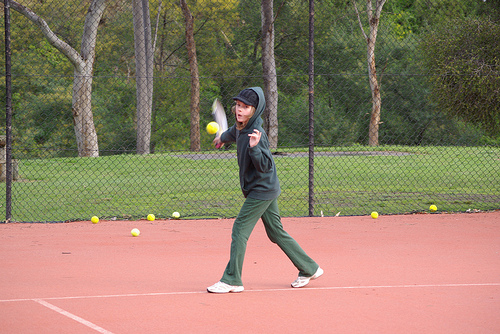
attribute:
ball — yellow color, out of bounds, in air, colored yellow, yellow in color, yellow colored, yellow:
[369, 210, 381, 222]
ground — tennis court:
[3, 203, 500, 332]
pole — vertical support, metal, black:
[306, 4, 318, 218]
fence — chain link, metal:
[4, 4, 499, 222]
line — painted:
[35, 296, 115, 330]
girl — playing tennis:
[207, 86, 325, 295]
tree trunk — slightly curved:
[362, 36, 387, 144]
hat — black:
[234, 86, 262, 107]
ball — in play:
[204, 119, 220, 135]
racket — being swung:
[209, 93, 234, 152]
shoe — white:
[293, 261, 327, 291]